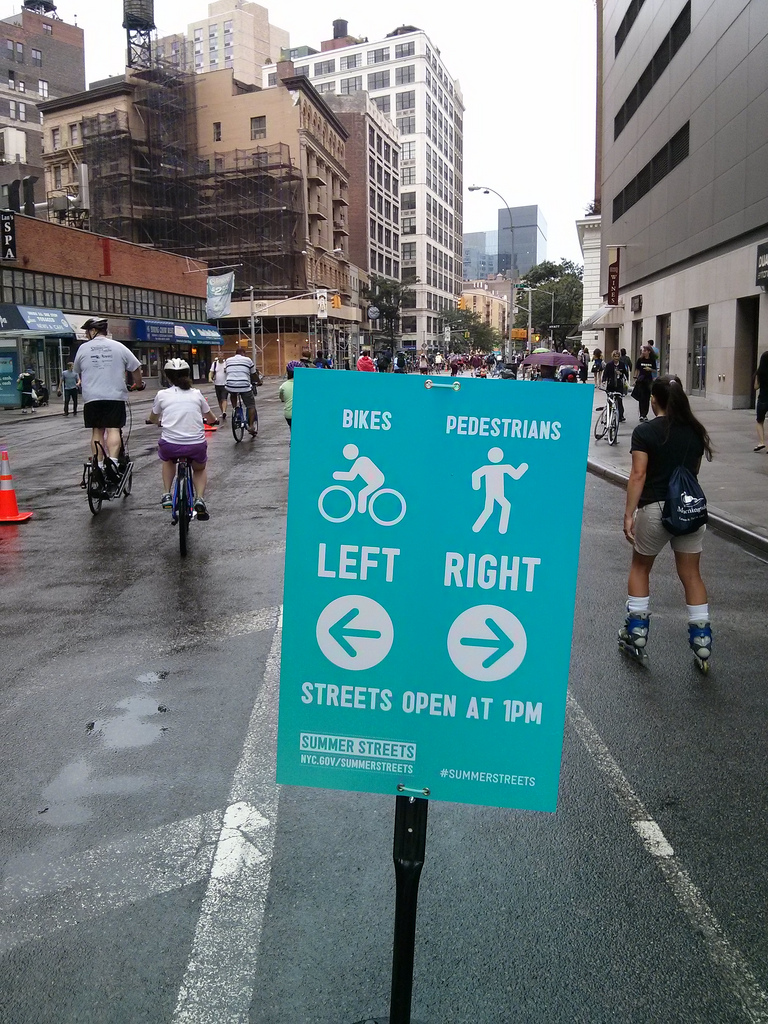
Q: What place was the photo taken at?
A: It was taken at the street.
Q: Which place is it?
A: It is a street.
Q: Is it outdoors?
A: Yes, it is outdoors.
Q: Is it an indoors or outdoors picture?
A: It is outdoors.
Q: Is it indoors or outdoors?
A: It is outdoors.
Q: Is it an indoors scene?
A: No, it is outdoors.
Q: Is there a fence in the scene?
A: No, there are no fences.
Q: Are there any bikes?
A: Yes, there is a bike.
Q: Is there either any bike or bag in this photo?
A: Yes, there is a bike.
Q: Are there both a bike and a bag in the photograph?
A: Yes, there are both a bike and a bag.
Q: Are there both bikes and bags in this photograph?
A: Yes, there are both a bike and a bag.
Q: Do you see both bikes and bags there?
A: Yes, there are both a bike and a bag.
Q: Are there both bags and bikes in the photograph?
A: Yes, there are both a bike and a bag.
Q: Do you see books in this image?
A: No, there are no books.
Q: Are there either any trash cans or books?
A: No, there are no books or trash cans.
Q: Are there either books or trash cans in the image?
A: No, there are no books or trash cans.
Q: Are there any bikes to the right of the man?
A: Yes, there is a bike to the right of the man.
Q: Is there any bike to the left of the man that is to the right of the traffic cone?
A: No, the bike is to the right of the man.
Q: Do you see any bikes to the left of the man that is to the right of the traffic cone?
A: No, the bike is to the right of the man.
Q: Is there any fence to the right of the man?
A: No, there is a bike to the right of the man.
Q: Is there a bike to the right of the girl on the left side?
A: Yes, there is a bike to the right of the girl.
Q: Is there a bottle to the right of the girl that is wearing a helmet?
A: No, there is a bike to the right of the girl.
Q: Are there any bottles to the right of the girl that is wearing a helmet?
A: No, there is a bike to the right of the girl.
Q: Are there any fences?
A: No, there are no fences.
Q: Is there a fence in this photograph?
A: No, there are no fences.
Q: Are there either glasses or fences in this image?
A: No, there are no fences or glasses.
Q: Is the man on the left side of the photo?
A: Yes, the man is on the left of the image.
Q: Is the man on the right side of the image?
A: No, the man is on the left of the image.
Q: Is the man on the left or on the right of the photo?
A: The man is on the left of the image.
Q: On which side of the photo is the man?
A: The man is on the left of the image.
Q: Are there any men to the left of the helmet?
A: Yes, there is a man to the left of the helmet.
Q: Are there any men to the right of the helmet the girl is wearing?
A: No, the man is to the left of the helmet.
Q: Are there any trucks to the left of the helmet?
A: No, there is a man to the left of the helmet.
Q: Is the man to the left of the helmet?
A: Yes, the man is to the left of the helmet.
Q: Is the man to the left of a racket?
A: No, the man is to the left of the helmet.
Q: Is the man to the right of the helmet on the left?
A: No, the man is to the left of the helmet.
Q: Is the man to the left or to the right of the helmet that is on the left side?
A: The man is to the left of the helmet.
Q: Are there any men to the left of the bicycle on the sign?
A: Yes, there is a man to the left of the bicycle.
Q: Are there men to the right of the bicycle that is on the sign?
A: No, the man is to the left of the bicycle.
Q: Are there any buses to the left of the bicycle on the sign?
A: No, there is a man to the left of the bicycle.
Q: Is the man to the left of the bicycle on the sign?
A: Yes, the man is to the left of the bicycle.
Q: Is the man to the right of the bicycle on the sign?
A: No, the man is to the left of the bicycle.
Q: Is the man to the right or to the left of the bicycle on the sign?
A: The man is to the left of the bicycle.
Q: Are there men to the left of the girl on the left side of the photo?
A: Yes, there is a man to the left of the girl.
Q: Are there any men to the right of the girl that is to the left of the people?
A: No, the man is to the left of the girl.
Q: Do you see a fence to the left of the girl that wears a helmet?
A: No, there is a man to the left of the girl.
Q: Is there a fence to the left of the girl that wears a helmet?
A: No, there is a man to the left of the girl.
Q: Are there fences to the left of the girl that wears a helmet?
A: No, there is a man to the left of the girl.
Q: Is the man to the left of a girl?
A: Yes, the man is to the left of a girl.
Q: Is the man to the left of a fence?
A: No, the man is to the left of a girl.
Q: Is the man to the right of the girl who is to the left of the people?
A: No, the man is to the left of the girl.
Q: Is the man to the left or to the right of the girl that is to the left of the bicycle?
A: The man is to the left of the girl.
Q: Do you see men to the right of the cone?
A: Yes, there is a man to the right of the cone.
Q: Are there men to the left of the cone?
A: No, the man is to the right of the cone.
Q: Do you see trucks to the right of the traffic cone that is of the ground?
A: No, there is a man to the right of the traffic cone.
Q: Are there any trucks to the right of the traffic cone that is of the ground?
A: No, there is a man to the right of the traffic cone.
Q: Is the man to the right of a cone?
A: Yes, the man is to the right of a cone.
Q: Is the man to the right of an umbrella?
A: No, the man is to the right of a cone.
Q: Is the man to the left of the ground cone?
A: No, the man is to the right of the cone.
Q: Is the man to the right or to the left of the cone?
A: The man is to the right of the cone.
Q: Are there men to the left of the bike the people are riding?
A: Yes, there is a man to the left of the bike.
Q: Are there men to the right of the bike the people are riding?
A: No, the man is to the left of the bike.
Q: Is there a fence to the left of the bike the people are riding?
A: No, there is a man to the left of the bike.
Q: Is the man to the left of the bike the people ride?
A: Yes, the man is to the left of the bike.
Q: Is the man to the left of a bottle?
A: No, the man is to the left of the bike.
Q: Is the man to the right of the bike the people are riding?
A: No, the man is to the left of the bike.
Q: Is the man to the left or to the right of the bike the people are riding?
A: The man is to the left of the bike.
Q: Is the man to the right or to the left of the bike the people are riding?
A: The man is to the left of the bike.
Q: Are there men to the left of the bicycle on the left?
A: Yes, there is a man to the left of the bicycle.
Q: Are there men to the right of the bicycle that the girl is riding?
A: No, the man is to the left of the bicycle.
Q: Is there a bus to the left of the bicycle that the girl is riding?
A: No, there is a man to the left of the bicycle.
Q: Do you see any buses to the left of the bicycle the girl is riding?
A: No, there is a man to the left of the bicycle.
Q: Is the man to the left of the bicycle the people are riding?
A: Yes, the man is to the left of the bicycle.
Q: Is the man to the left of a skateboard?
A: No, the man is to the left of the bicycle.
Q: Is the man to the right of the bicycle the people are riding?
A: No, the man is to the left of the bicycle.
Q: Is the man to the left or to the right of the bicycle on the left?
A: The man is to the left of the bicycle.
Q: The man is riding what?
A: The man is riding a bike.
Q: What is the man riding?
A: The man is riding a bike.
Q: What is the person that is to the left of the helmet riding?
A: The man is riding a bike.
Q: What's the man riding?
A: The man is riding a bike.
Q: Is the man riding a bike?
A: Yes, the man is riding a bike.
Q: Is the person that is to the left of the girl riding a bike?
A: Yes, the man is riding a bike.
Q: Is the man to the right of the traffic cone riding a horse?
A: No, the man is riding a bike.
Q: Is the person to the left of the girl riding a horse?
A: No, the man is riding a bike.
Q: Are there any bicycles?
A: Yes, there is a bicycle.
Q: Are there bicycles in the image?
A: Yes, there is a bicycle.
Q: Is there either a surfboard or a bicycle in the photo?
A: Yes, there is a bicycle.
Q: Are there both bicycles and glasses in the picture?
A: No, there is a bicycle but no glasses.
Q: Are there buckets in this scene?
A: No, there are no buckets.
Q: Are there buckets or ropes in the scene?
A: No, there are no buckets or ropes.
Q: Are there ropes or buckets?
A: No, there are no buckets or ropes.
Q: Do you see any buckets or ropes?
A: No, there are no buckets or ropes.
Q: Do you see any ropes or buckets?
A: No, there are no buckets or ropes.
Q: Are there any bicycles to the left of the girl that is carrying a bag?
A: Yes, there is a bicycle to the left of the girl.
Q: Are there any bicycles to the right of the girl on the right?
A: No, the bicycle is to the left of the girl.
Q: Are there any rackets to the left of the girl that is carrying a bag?
A: No, there is a bicycle to the left of the girl.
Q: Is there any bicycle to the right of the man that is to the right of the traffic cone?
A: Yes, there is a bicycle to the right of the man.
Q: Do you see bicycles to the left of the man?
A: No, the bicycle is to the right of the man.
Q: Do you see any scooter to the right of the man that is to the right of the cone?
A: No, there is a bicycle to the right of the man.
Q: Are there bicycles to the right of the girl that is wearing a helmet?
A: Yes, there is a bicycle to the right of the girl.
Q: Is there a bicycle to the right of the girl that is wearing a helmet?
A: Yes, there is a bicycle to the right of the girl.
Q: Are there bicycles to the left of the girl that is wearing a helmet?
A: No, the bicycle is to the right of the girl.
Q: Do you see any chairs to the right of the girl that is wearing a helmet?
A: No, there is a bicycle to the right of the girl.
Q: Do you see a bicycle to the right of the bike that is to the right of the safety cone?
A: Yes, there is a bicycle to the right of the bike.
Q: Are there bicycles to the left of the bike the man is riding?
A: No, the bicycle is to the right of the bike.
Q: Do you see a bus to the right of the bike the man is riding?
A: No, there is a bicycle to the right of the bike.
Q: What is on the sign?
A: The bicycle is on the sign.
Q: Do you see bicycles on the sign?
A: Yes, there is a bicycle on the sign.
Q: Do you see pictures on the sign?
A: No, there is a bicycle on the sign.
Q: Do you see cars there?
A: No, there are no cars.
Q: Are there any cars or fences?
A: No, there are no cars or fences.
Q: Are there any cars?
A: No, there are no cars.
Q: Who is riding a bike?
A: The people are riding a bike.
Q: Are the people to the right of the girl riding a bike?
A: Yes, the people are riding a bike.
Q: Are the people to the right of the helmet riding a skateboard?
A: No, the people are riding a bike.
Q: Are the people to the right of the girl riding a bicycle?
A: Yes, the people are riding a bicycle.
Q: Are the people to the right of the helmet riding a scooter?
A: No, the people are riding a bicycle.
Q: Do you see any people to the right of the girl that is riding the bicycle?
A: Yes, there are people to the right of the girl.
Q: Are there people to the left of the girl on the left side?
A: No, the people are to the right of the girl.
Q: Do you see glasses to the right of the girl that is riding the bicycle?
A: No, there are people to the right of the girl.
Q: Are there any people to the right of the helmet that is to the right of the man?
A: Yes, there are people to the right of the helmet.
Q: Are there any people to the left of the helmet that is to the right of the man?
A: No, the people are to the right of the helmet.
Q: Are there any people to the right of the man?
A: Yes, there are people to the right of the man.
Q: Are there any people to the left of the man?
A: No, the people are to the right of the man.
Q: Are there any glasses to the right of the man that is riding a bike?
A: No, there are people to the right of the man.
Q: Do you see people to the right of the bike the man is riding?
A: Yes, there are people to the right of the bike.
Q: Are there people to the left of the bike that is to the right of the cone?
A: No, the people are to the right of the bike.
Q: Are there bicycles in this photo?
A: Yes, there is a bicycle.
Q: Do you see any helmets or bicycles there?
A: Yes, there is a bicycle.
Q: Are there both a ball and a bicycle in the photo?
A: No, there is a bicycle but no balls.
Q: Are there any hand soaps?
A: No, there are no hand soaps.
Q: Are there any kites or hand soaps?
A: No, there are no hand soaps or kites.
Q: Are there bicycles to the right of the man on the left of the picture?
A: Yes, there is a bicycle to the right of the man.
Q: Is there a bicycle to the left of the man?
A: No, the bicycle is to the right of the man.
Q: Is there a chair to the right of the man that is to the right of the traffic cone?
A: No, there is a bicycle to the right of the man.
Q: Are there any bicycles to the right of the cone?
A: Yes, there is a bicycle to the right of the cone.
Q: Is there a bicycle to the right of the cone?
A: Yes, there is a bicycle to the right of the cone.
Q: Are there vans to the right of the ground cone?
A: No, there is a bicycle to the right of the traffic cone.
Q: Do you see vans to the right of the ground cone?
A: No, there is a bicycle to the right of the traffic cone.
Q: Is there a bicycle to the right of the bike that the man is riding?
A: Yes, there is a bicycle to the right of the bike.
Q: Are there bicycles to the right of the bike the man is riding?
A: Yes, there is a bicycle to the right of the bike.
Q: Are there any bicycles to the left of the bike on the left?
A: No, the bicycle is to the right of the bike.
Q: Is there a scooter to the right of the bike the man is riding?
A: No, there is a bicycle to the right of the bike.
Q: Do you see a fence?
A: No, there are no fences.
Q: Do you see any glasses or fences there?
A: No, there are no fences or glasses.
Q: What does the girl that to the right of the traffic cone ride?
A: The girl rides the bicycle.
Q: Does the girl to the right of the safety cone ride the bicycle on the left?
A: Yes, the girl rides the bicycle.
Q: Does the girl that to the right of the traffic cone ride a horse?
A: No, the girl rides the bicycle.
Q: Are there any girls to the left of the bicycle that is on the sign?
A: Yes, there is a girl to the left of the bicycle.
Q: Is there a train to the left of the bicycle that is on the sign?
A: No, there is a girl to the left of the bicycle.